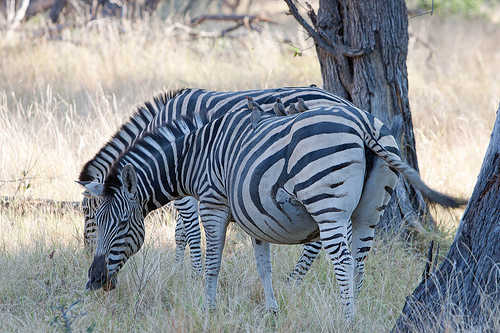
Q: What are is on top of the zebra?
A: Birds.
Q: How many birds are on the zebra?
A: Four.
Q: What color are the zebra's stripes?
A: Black.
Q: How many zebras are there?
A: Two.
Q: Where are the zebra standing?
A: In Between two trees.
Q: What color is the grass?
A: Brown.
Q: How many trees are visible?
A: Two.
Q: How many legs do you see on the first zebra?
A: Four.